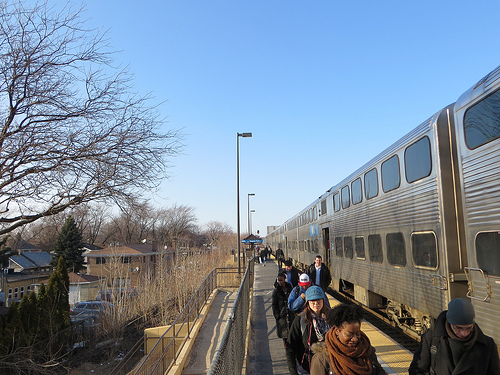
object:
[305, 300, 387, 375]
person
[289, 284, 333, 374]
person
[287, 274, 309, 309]
person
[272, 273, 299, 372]
person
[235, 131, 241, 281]
post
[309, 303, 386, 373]
woman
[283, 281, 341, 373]
person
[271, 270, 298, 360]
person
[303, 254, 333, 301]
person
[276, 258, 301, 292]
person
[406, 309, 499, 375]
coat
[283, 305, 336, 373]
coat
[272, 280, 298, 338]
coat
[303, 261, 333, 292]
coat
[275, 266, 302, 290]
coat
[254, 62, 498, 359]
train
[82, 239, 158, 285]
houses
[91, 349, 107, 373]
litter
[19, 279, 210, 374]
ground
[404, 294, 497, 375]
passengers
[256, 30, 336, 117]
white clouds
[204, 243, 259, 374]
fence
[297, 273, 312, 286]
cap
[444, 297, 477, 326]
hat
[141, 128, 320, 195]
clouds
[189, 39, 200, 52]
clouds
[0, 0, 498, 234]
sky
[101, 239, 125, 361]
trees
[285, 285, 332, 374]
woman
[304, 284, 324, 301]
cap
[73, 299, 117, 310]
cars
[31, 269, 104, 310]
building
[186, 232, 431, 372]
station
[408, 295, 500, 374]
person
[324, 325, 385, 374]
scarf